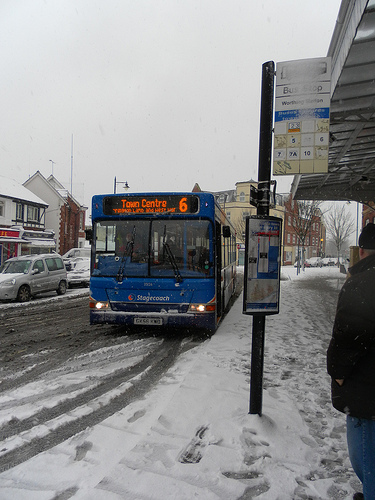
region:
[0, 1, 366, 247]
A light grey sky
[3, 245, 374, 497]
Snow on the ground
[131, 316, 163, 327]
A white and black license plate on the front of a bus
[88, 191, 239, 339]
A blue bus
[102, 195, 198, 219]
A lit up bus display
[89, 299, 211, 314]
Headlights turned on.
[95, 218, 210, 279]
A windshield on a bus.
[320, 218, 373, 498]
A person standing on the sidewalk.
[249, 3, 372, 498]
A bus stop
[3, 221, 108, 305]
Vehicles parked on the side of the road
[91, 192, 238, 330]
Public bus going to the Town Centre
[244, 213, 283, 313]
Informational sign at a bus stop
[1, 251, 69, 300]
Small SUV parked on the side of the road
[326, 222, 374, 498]
Man in a black jacket and a hat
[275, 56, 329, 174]
Hanging bus stop sign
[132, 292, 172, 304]
Stage coach logo on a bus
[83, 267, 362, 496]
Snowy sidewalk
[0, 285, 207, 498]
Snow covered road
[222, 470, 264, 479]
One footprint in the snow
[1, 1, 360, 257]
Gray and dreary sky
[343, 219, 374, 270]
the head of a man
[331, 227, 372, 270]
the ear of a man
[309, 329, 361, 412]
the hand of a man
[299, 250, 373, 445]
the arm of a man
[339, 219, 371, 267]
a man wearing a coat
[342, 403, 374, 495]
a man wearing pants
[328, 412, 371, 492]
a man wearing blue jeans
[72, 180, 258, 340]
the front of a bus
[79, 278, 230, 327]
the headlights on a bus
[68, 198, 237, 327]
the windshield on a bus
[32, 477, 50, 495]
Tracks in the white snow on the ground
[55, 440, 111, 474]
Tracks in the white snow on the ground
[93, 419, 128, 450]
Tracks in the white snow on the ground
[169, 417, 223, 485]
Tracks in the white snow on the ground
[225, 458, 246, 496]
Tracks in the white snow on the ground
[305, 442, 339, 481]
Tracks in the white snow on the ground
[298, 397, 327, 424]
Tracks in the white snow on the ground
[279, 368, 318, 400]
Tracks in the white snow on the ground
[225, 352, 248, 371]
Tracks in the white snow on the ground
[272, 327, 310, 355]
Tracks in the white snow on the ground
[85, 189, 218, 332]
The front of a bus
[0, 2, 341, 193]
The sky appears very overcast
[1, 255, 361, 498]
White snow is on the ground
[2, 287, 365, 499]
Footprints are on the snow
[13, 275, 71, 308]
Two round black tires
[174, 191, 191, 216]
Number 6 on the bus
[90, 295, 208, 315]
Two headlights are turned on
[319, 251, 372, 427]
The jacket is black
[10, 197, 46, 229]
Windows on a building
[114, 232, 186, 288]
Two black windshield wipers